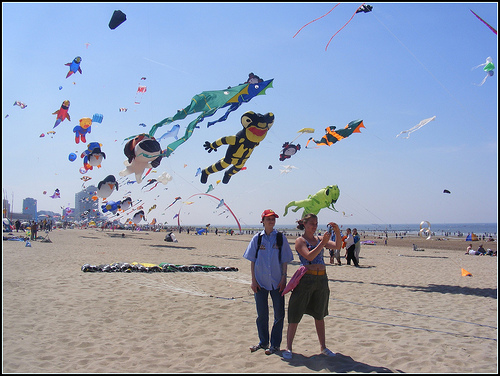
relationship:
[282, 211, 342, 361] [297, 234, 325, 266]
lady wearing shirt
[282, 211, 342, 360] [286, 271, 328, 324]
lady wearing green shorts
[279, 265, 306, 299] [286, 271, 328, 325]
pink scarf tied on green shorts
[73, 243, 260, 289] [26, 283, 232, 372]
kite laying in sand